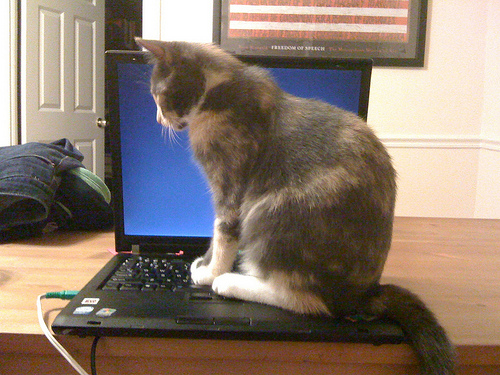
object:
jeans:
[0, 137, 88, 232]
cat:
[131, 33, 461, 375]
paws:
[207, 268, 238, 297]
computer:
[39, 35, 412, 338]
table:
[0, 212, 496, 374]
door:
[18, 0, 113, 202]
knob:
[95, 116, 113, 130]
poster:
[205, 3, 433, 72]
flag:
[230, 4, 412, 47]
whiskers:
[168, 117, 175, 150]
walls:
[367, 0, 499, 225]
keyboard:
[97, 252, 239, 296]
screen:
[111, 62, 368, 236]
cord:
[46, 287, 79, 301]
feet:
[191, 256, 284, 307]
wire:
[88, 339, 99, 372]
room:
[0, 0, 500, 375]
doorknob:
[96, 115, 115, 137]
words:
[270, 43, 275, 50]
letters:
[159, 268, 177, 282]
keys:
[141, 283, 157, 291]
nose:
[152, 113, 165, 125]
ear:
[128, 34, 173, 65]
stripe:
[218, 0, 414, 33]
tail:
[370, 283, 468, 374]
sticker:
[82, 295, 102, 307]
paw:
[189, 263, 218, 287]